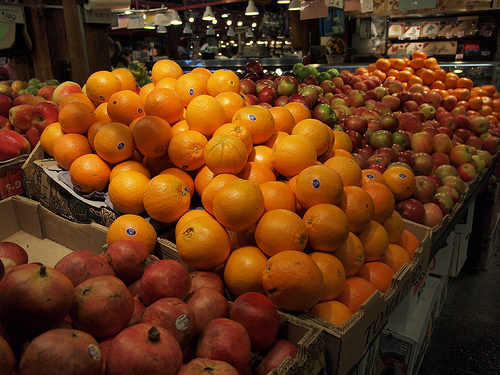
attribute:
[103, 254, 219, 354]
pomengrantes — red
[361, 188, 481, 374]
boxes — white, cardboard